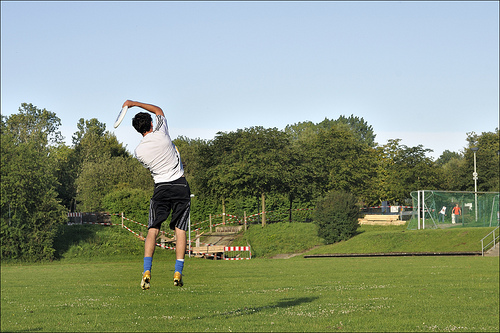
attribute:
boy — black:
[123, 78, 207, 264]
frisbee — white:
[105, 91, 139, 128]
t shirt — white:
[79, 110, 218, 188]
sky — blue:
[203, 26, 265, 70]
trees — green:
[22, 149, 124, 186]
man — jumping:
[114, 120, 223, 224]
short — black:
[126, 98, 190, 179]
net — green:
[406, 191, 458, 222]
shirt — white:
[133, 128, 179, 172]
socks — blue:
[137, 259, 184, 275]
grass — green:
[251, 254, 359, 287]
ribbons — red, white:
[213, 208, 249, 250]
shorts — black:
[145, 166, 197, 228]